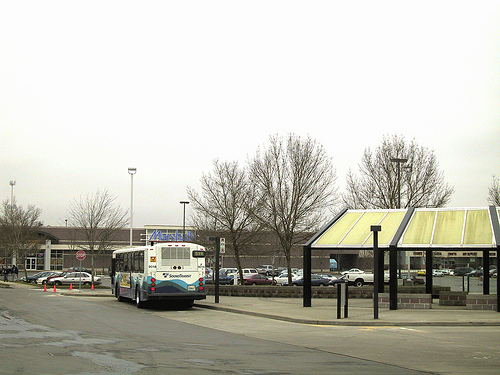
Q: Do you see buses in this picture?
A: Yes, there is a bus.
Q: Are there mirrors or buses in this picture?
A: Yes, there is a bus.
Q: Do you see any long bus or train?
A: Yes, there is a long bus.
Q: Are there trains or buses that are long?
A: Yes, the bus is long.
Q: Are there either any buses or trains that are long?
A: Yes, the bus is long.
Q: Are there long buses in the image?
A: Yes, there is a long bus.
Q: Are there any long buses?
A: Yes, there is a long bus.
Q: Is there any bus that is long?
A: Yes, there is a bus that is long.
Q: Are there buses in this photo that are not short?
A: Yes, there is a long bus.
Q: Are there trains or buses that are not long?
A: No, there is a bus but it is long.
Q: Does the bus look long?
A: Yes, the bus is long.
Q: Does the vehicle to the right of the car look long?
A: Yes, the bus is long.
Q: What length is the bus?
A: The bus is long.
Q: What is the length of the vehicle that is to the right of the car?
A: The bus is long.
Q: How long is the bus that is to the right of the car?
A: The bus is long.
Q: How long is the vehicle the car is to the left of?
A: The bus is long.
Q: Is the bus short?
A: No, the bus is long.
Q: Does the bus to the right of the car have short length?
A: No, the bus is long.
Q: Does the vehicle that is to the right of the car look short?
A: No, the bus is long.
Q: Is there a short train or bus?
A: No, there is a bus but it is long.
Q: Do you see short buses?
A: No, there is a bus but it is long.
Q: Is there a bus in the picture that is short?
A: No, there is a bus but it is long.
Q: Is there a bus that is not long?
A: No, there is a bus but it is long.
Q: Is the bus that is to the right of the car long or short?
A: The bus is long.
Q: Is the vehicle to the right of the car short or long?
A: The bus is long.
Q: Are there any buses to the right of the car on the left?
A: Yes, there is a bus to the right of the car.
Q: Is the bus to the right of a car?
A: Yes, the bus is to the right of a car.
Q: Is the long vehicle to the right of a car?
A: Yes, the bus is to the right of a car.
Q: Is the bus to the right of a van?
A: No, the bus is to the right of a car.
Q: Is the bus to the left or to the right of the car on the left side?
A: The bus is to the right of the car.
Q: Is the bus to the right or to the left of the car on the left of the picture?
A: The bus is to the right of the car.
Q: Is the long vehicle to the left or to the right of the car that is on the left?
A: The bus is to the right of the car.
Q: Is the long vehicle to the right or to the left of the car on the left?
A: The bus is to the right of the car.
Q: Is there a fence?
A: No, there are no fences.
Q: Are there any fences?
A: No, there are no fences.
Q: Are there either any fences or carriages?
A: No, there are no fences or carriages.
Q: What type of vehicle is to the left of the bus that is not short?
A: The vehicle is a car.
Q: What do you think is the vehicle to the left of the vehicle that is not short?
A: The vehicle is a car.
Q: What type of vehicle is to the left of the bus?
A: The vehicle is a car.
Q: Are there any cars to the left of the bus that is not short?
A: Yes, there is a car to the left of the bus.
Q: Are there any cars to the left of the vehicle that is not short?
A: Yes, there is a car to the left of the bus.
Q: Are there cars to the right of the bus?
A: No, the car is to the left of the bus.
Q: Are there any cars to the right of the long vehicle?
A: No, the car is to the left of the bus.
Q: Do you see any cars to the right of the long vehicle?
A: No, the car is to the left of the bus.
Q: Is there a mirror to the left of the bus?
A: No, there is a car to the left of the bus.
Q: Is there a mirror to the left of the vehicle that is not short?
A: No, there is a car to the left of the bus.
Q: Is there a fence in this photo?
A: No, there are no fences.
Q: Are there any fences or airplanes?
A: No, there are no fences or airplanes.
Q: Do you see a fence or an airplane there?
A: No, there are no fences or airplanes.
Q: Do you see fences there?
A: No, there are no fences.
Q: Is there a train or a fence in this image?
A: No, there are no fences or trains.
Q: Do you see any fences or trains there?
A: No, there are no fences or trains.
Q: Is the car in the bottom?
A: Yes, the car is in the bottom of the image.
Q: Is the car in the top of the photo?
A: No, the car is in the bottom of the image.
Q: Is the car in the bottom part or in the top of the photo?
A: The car is in the bottom of the image.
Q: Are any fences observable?
A: No, there are no fences.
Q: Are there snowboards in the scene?
A: No, there are no snowboards.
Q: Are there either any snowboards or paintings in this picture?
A: No, there are no snowboards or paintings.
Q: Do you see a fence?
A: No, there are no fences.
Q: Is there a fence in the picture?
A: No, there are no fences.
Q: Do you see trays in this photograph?
A: No, there are no trays.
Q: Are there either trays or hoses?
A: No, there are no trays or hoses.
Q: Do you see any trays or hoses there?
A: No, there are no trays or hoses.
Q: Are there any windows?
A: Yes, there is a window.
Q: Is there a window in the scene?
A: Yes, there is a window.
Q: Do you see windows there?
A: Yes, there is a window.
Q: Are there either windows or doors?
A: Yes, there is a window.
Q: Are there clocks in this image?
A: No, there are no clocks.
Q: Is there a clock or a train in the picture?
A: No, there are no clocks or trains.